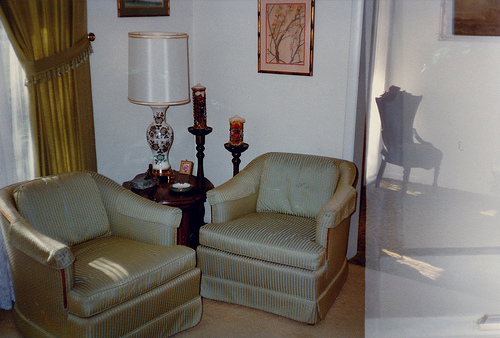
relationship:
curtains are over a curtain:
[1, 0, 100, 179] [2, 7, 107, 180]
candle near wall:
[187, 82, 213, 193] [189, 0, 351, 226]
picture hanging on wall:
[257, 9, 297, 74] [202, 0, 352, 187]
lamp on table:
[128, 30, 191, 176] [117, 166, 216, 248]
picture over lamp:
[105, 2, 182, 22] [128, 30, 191, 176]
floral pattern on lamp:
[146, 109, 173, 170] [119, 29, 195, 188]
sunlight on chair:
[93, 256, 128, 281] [0, 168, 201, 328]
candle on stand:
[187, 82, 213, 193] [188, 125, 213, 182]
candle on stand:
[227, 112, 244, 145] [221, 140, 249, 177]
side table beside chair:
[122, 169, 215, 249] [0, 140, 202, 337]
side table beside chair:
[122, 169, 215, 249] [192, 142, 370, 334]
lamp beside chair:
[124, 24, 192, 204] [202, 151, 356, 316]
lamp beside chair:
[124, 24, 192, 204] [0, 168, 201, 328]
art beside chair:
[114, 0, 174, 20] [192, 142, 370, 334]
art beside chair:
[114, 0, 174, 20] [0, 168, 201, 328]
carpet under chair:
[0, 261, 374, 338] [191, 146, 363, 326]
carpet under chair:
[0, 261, 374, 338] [0, 168, 201, 328]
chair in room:
[195, 151, 359, 326] [0, 0, 498, 335]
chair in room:
[0, 170, 204, 337] [0, 0, 498, 335]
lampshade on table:
[105, 17, 225, 177] [126, 140, 236, 267]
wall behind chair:
[83, 1, 356, 261] [191, 146, 363, 326]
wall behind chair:
[83, 1, 356, 261] [0, 168, 201, 328]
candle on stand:
[187, 82, 213, 193] [188, 126, 213, 177]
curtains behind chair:
[1, 0, 98, 310] [0, 168, 201, 328]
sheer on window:
[0, 24, 38, 310] [1, 29, 53, 196]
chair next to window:
[0, 168, 201, 328] [0, 0, 72, 188]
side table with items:
[122, 169, 215, 249] [121, 143, 207, 196]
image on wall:
[251, 0, 343, 64] [195, 3, 358, 152]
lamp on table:
[128, 30, 191, 176] [120, 166, 216, 265]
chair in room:
[369, 82, 450, 218] [22, 18, 487, 327]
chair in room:
[191, 146, 363, 326] [22, 18, 487, 327]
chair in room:
[0, 168, 201, 328] [22, 18, 487, 327]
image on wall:
[439, 1, 499, 43] [380, 0, 497, 201]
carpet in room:
[199, 286, 361, 336] [63, 5, 491, 333]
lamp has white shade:
[128, 30, 191, 176] [127, 33, 188, 105]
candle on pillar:
[186, 82, 210, 127] [182, 117, 213, 199]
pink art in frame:
[256, 2, 316, 77] [255, 0, 320, 81]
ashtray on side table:
[166, 178, 197, 196] [122, 164, 222, 250]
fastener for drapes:
[84, 29, 94, 41] [0, 0, 93, 185]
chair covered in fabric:
[191, 146, 363, 326] [258, 163, 318, 217]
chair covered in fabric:
[0, 168, 201, 328] [0, 180, 107, 237]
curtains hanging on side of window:
[1, 0, 100, 179] [0, 33, 38, 311]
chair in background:
[375, 84, 444, 197] [369, 11, 484, 286]